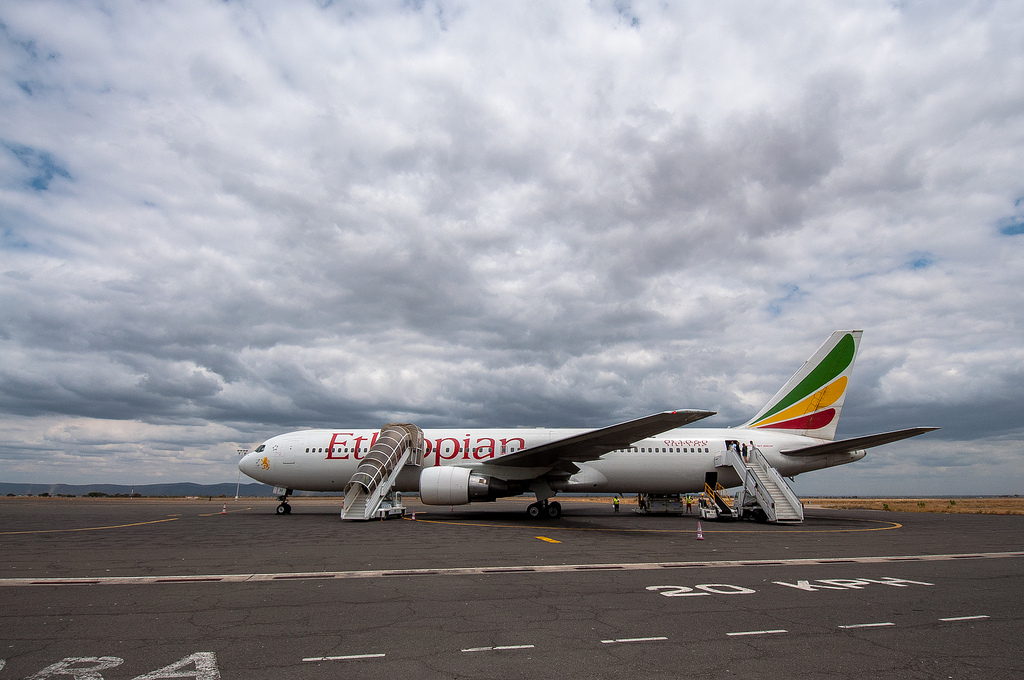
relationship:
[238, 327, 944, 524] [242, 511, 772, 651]
aircraft on runway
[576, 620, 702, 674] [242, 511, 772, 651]
line on runway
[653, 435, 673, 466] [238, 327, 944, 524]
window on aircraft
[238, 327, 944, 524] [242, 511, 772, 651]
aircraft in runway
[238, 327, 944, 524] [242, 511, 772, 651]
aircraft near runway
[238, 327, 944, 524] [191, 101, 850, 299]
aircraft below sky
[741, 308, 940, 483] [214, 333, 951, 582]
tail of jet aircraft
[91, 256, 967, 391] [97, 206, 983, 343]
sky shows heavy cloud banks